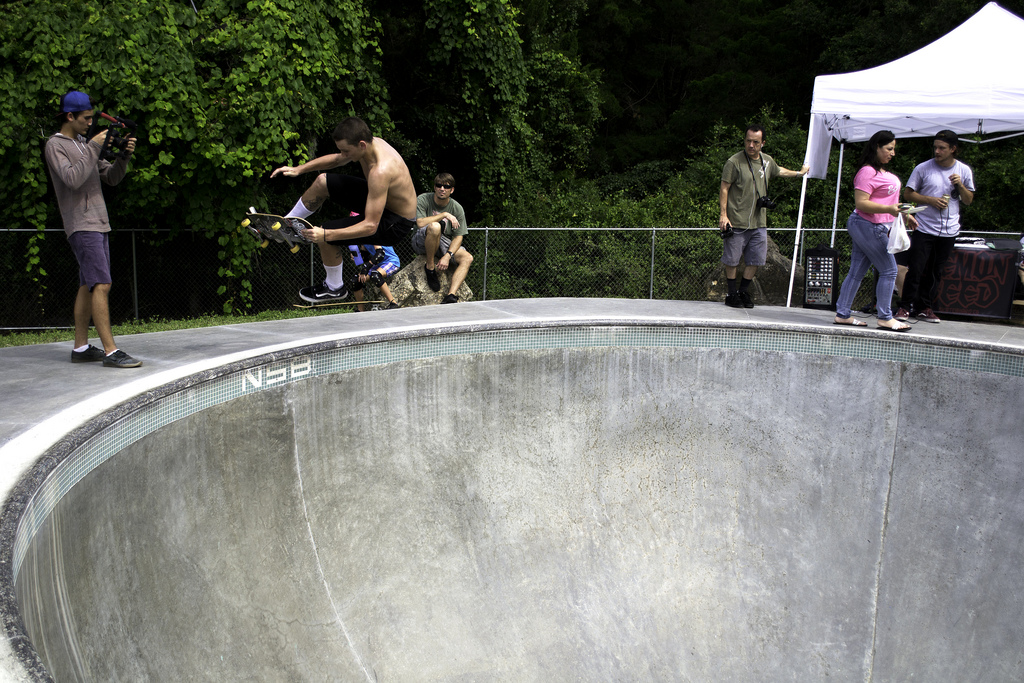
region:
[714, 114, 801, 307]
Man standing with arm on pole.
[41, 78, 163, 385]
Young man with video camera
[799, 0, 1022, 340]
White tent with two people underneath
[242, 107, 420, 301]
Young man skateboarding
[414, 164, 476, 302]
Young man with sunglasses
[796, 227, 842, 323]
Electronic equipment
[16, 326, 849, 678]
Skateboarding pit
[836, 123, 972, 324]
Two people talking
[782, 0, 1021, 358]
A white canopy tent.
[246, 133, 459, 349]
A skateboarder.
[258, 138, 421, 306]
A guy doing a trick on a skateboard.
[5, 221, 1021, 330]
A grey chainlink fence.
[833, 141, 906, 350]
A woman wearing a pink shirt.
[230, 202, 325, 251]
A skateboard.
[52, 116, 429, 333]
A man photographing a skateboarder.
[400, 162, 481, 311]
A guy sitting on a rock.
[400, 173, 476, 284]
A guy wearing black sunglasses.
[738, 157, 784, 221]
A black camera with a black strap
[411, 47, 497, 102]
green leaves on the tree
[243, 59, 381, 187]
green leaves on the tree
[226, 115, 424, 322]
skater doing tricks in course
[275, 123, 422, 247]
skater not wearing shirt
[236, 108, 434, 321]
skater holding skateboard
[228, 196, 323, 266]
skateboard under right foot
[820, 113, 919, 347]
woman walking by skate course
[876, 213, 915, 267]
plastic bag is small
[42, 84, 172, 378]
man is taking videos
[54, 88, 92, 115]
man wearing blue baseball cap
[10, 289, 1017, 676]
concrete skating course in skate park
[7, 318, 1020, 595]
many small green tiles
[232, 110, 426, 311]
skateboarder up in air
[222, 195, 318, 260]
skateboard beneath boy's feet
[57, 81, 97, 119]
blue ball cap covering boy's head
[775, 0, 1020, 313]
white awning tent providing shade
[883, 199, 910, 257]
white bag in woman's right hand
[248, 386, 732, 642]
lines on the skate park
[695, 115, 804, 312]
A person is standing up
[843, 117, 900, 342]
A person is standing up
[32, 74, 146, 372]
a person is standing up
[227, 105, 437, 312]
a person is playing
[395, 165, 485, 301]
a person is sitting down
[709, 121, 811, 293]
a person is standing up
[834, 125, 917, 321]
a person is standing up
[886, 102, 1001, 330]
a person is standing up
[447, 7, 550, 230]
a tree in the woods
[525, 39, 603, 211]
a tree in the woods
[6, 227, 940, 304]
a silver chain link fence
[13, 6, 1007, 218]
trees behind the fence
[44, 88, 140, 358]
a man in a blue hat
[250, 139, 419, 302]
a man jumping on a skateboard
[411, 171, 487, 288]
a man sitting on a rock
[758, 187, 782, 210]
a black camera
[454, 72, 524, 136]
green leaves on the tree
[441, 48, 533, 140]
green leaves on the tree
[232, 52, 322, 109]
green leaves on the tree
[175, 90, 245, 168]
green leaves on the tree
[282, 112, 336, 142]
green leaves on the tree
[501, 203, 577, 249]
green leaves on the tree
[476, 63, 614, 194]
green leaves on the tree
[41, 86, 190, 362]
Man in blue cap